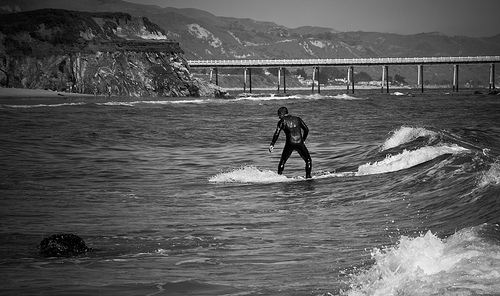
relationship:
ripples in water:
[362, 176, 448, 216] [294, 159, 437, 267]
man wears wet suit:
[265, 104, 315, 180] [278, 115, 305, 143]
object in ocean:
[33, 229, 93, 264] [0, 99, 500, 296]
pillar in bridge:
[209, 66, 221, 88] [185, 55, 497, 91]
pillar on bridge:
[261, 67, 285, 102] [344, 60, 358, 94]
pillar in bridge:
[449, 67, 460, 90] [193, 53, 498, 95]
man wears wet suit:
[268, 106, 313, 179] [265, 113, 317, 175]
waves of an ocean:
[330, 67, 498, 272] [0, 90, 497, 294]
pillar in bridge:
[416, 59, 425, 88] [188, 49, 498, 96]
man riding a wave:
[268, 106, 313, 179] [353, 118, 498, 247]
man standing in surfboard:
[268, 106, 313, 179] [284, 166, 336, 181]